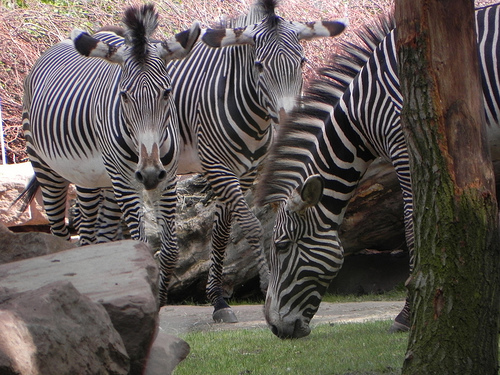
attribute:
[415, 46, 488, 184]
trunk — brown, sliced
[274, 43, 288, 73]
markings — brown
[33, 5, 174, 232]
zebra — eating, white, black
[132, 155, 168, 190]
nose — black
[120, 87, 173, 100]
eyes — dark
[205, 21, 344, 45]
ears — white, black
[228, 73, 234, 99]
hair — black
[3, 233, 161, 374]
rocks — gray, large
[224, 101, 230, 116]
hair — white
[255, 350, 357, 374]
grass — green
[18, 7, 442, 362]
zebras — walking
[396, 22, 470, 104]
tree — large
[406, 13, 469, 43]
tree trunk — brown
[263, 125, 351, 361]
zebra — eating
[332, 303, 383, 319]
ground — grass, stone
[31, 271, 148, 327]
stones — large